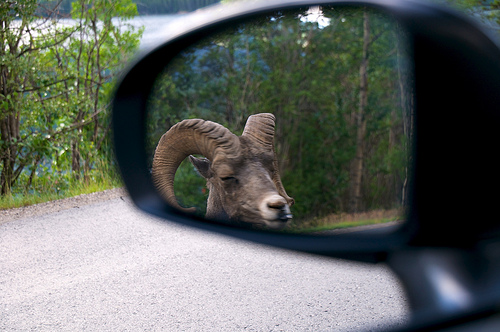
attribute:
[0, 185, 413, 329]
road — grey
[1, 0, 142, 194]
trees — green, leafy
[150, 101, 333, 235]
sheep — brown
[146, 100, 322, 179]
horns — large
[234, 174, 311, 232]
snout — white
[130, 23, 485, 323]
car — driving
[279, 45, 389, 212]
mirror — clear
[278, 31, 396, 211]
mirror — clear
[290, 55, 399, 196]
mirror — clear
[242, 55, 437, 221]
mirror — clear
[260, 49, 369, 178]
mirror — clear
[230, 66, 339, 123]
mirror — clear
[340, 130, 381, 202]
mirror — clear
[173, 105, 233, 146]
mirror — clear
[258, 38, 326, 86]
mirror — clear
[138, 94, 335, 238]
head — reflected, rams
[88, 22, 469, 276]
mirror — sideview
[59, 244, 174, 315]
roadway — paved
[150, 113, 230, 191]
horn — curved, rams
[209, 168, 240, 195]
eye — closed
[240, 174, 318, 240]
nose — white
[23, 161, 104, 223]
grass — growing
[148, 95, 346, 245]
goat — mountain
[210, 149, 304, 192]
eyes — closed